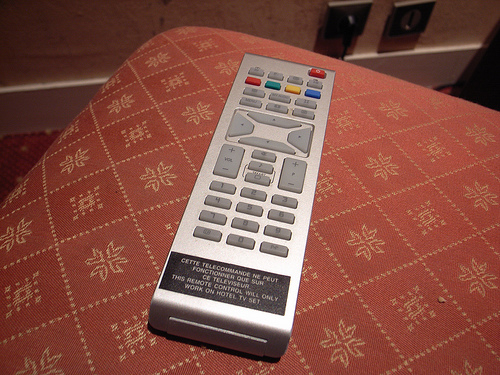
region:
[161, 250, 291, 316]
Writing on the remote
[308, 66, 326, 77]
The power button on the remote control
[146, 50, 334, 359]
The remote control is silver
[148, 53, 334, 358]
The remote control is on the bed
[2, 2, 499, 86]
A wall by the bed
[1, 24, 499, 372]
A bed beneath the remote control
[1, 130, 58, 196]
The floor beneath the bed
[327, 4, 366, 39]
An outlet on the wall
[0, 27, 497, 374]
A sheet on the bed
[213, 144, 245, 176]
The volume control on the remote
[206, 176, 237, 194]
The number on the remote controll is black.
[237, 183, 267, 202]
The number on the remote controll is black.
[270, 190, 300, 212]
The number on the remote controll is black.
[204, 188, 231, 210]
The number on the remote controll is black.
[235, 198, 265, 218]
The number on the remote controll is black.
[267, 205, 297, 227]
The number on the remote controll is black.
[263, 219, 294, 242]
The number on the remote controll is black.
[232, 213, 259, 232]
The number on the remote controll is black.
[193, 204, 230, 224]
The number on the remote controll is black.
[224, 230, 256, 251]
The number on the remote controll is black.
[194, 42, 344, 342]
A grey remote control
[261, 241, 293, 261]
A grey remote control's button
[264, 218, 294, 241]
A grey remote control's button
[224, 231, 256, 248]
A grey remote control's button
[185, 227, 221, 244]
A grey remote control's button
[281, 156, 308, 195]
A grey remote control's button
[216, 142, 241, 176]
A grey remote control's button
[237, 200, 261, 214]
A grey remote control's button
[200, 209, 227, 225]
A grey remote control's button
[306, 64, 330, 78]
A grey remote control's button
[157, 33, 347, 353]
The remote is silver.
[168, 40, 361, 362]
The remote is on the chair.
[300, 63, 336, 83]
The remote has a red button.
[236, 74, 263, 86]
The remote has a red button.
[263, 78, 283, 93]
The remote has a green button.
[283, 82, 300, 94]
The remote has a yellow button.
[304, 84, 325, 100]
The remote has a blue button.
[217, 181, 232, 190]
The number on the button is black.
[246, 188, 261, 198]
The number on the button is black.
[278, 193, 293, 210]
The number on the button is black.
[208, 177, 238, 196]
The number is black.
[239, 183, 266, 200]
The number is black.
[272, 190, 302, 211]
The number is black.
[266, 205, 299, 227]
The number is black.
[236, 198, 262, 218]
The number is black.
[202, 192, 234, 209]
The number is black.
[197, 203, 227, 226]
The number is black.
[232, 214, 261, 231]
The number is black.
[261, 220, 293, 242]
The number is black.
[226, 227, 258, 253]
The number is black.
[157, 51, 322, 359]
Silver television remote control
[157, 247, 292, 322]
Writing on remote control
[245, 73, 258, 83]
Orange button on remote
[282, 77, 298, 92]
Yellow button on remote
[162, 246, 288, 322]
black sticker on remote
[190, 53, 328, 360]
Remote control on chair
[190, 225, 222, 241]
grey button on the silver remote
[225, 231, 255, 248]
grey button on the silver remote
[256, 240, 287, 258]
grey button on the silver remote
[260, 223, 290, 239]
grey button on the silver remote